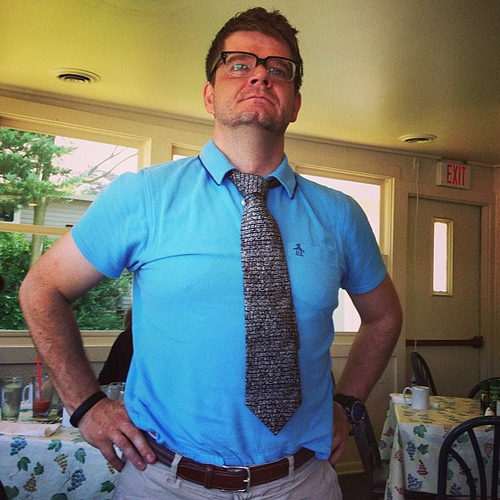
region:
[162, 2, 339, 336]
man wearing blue shirt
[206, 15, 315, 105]
man wearing horn rimmed glasses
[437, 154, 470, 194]
exit sign above door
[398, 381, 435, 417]
white coffee mug on table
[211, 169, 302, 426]
man wearing tie and polo shirt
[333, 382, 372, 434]
man wearing black watch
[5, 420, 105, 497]
tablecloths with grape pattern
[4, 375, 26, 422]
glass of water on table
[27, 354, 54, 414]
glass with red straw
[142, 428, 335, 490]
man wearing brown belt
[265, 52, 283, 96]
This man is wearing a pair of glasses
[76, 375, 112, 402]
This man is wearing a black bracelet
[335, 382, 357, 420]
This man is wearing a wristwatch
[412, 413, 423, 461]
There is a tablecloth that is here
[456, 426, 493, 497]
There are green chairs here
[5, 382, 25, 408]
There is some water here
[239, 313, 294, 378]
There is a tie that is visible here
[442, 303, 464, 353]
There is a cream-colored door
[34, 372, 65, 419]
There is a strawberry drink here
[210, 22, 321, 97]
man wearing glasses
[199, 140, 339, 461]
the man wearing tie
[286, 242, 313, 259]
logo on the shirt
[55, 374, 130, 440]
band on the wrist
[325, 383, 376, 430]
the watch on the wrist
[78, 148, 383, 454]
man wearing polo shirt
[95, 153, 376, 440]
the shirt is blue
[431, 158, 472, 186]
exit sign over the door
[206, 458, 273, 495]
buckle on the belt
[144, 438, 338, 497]
the belt is brown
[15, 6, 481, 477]
man posing for a photograph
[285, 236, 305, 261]
logo on his shirt pocket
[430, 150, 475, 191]
exit sign in a restaurant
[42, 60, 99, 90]
speaker set in the ceiling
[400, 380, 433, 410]
white coffee cup on the table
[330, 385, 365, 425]
watch on his wrist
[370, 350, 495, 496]
empty table with chair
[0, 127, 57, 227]
tree outside the window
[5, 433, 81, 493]
design pattern on a table cloth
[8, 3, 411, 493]
The man standing in the dining area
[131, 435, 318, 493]
The man is wearing a brown belt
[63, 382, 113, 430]
The man is wearing a black arm band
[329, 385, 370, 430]
The man has on a watch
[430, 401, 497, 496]
The chair at the table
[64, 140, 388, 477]
The man has on a blue shirt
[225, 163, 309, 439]
The man has on a tie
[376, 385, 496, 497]
The table has a table cloth on it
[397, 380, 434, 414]
A coffee cup on the table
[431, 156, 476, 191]
The exit sign on the door